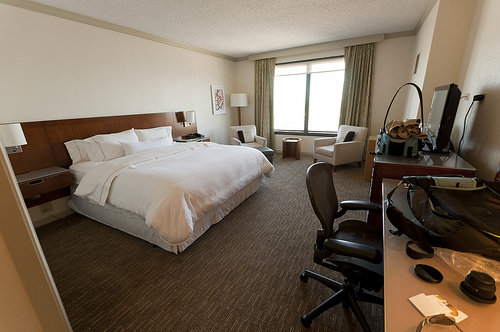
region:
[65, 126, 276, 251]
King size bed with white comforter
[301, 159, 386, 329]
Wheeled office chair with arm rests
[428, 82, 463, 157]
Black flat screen tv on dresser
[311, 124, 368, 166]
White upholstered chair with wooden legs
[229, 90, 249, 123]
White cylindrical lamp with wooden base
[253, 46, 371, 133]
Large window with tan hanging drapes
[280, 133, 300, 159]
Small cylindrical wood side table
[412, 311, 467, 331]
Light brown pair of curved sunglasses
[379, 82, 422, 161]
Blue nylon bag with multiple pockets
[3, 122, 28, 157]
White lamp attached to wall near bed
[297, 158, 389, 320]
a black swivel chair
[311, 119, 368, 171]
a white chair by a window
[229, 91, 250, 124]
a lamp in a corner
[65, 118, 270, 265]
a white bed in a room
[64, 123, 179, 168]
a set of pillows on a bed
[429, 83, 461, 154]
a tv on a table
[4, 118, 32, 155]
a light on a wall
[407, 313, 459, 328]
a pair of glasses on a table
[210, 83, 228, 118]
a picture on a wall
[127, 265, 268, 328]
a brown and tan carpet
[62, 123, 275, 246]
this is a bed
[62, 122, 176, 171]
these are some pillows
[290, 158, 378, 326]
this is a chair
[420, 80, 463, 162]
this is a television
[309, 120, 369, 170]
this is a chair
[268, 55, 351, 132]
this is a window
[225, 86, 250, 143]
this is a lamp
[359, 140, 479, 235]
this is a television stand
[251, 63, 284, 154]
this is a curtain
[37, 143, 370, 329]
this is the carpet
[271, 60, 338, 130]
a large window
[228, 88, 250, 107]
a white lampshade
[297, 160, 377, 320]
a black computer chair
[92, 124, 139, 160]
a white pillow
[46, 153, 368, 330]
a section of carpet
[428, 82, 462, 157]
a black t.v.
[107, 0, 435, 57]
part of a white ceiling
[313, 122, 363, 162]
a white living room chair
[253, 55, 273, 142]
a long green curtain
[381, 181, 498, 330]
part of a long brown desk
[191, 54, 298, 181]
The chair is in the corner of the room.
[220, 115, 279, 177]
The chair is empty.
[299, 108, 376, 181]
The chair is empty.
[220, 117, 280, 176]
The chair is white.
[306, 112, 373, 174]
The chair is white.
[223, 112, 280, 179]
The chair is unoccupied.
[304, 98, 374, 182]
The chair is unoccupied.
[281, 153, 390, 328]
The chair is unoccupied.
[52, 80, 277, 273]
The bed is unoccupied.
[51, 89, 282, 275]
The bed is neatly made.